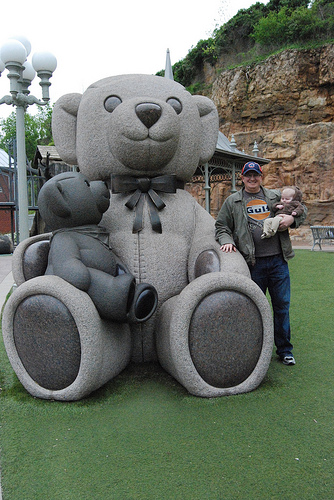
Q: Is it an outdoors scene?
A: Yes, it is outdoors.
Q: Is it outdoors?
A: Yes, it is outdoors.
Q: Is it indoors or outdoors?
A: It is outdoors.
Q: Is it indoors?
A: No, it is outdoors.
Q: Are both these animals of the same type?
A: Yes, all the animals are bears.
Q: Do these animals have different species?
A: No, all the animals are bears.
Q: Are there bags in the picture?
A: No, there are no bags.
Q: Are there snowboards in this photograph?
A: No, there are no snowboards.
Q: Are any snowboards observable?
A: No, there are no snowboards.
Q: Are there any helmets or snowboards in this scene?
A: No, there are no snowboards or helmets.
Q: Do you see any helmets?
A: No, there are no helmets.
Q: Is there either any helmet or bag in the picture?
A: No, there are no helmets or bags.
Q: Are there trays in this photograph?
A: No, there are no trays.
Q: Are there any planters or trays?
A: No, there are no trays or planters.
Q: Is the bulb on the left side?
A: Yes, the bulb is on the left of the image.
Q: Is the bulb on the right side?
A: No, the bulb is on the left of the image.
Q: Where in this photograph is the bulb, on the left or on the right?
A: The bulb is on the left of the image.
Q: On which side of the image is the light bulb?
A: The light bulb is on the left of the image.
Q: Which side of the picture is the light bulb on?
A: The light bulb is on the left of the image.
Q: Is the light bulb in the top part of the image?
A: Yes, the light bulb is in the top of the image.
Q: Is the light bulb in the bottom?
A: No, the light bulb is in the top of the image.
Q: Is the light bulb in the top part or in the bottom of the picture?
A: The light bulb is in the top of the image.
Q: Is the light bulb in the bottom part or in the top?
A: The light bulb is in the top of the image.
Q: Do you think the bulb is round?
A: Yes, the bulb is round.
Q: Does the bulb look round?
A: Yes, the bulb is round.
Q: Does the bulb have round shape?
A: Yes, the bulb is round.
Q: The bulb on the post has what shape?
A: The light bulb is round.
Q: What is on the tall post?
A: The bulb is on the post.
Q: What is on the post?
A: The bulb is on the post.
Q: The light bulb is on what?
A: The light bulb is on the post.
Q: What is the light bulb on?
A: The light bulb is on the post.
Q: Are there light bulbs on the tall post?
A: Yes, there is a light bulb on the post.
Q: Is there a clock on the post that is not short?
A: No, there is a light bulb on the post.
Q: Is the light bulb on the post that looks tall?
A: Yes, the light bulb is on the post.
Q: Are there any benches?
A: Yes, there is a bench.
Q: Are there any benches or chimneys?
A: Yes, there is a bench.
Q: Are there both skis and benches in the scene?
A: No, there is a bench but no skis.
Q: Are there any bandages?
A: No, there are no bandages.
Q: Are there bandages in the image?
A: No, there are no bandages.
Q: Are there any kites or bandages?
A: No, there are no bandages or kites.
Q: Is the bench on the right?
A: Yes, the bench is on the right of the image.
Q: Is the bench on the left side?
A: No, the bench is on the right of the image.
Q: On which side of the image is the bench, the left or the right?
A: The bench is on the right of the image.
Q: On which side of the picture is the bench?
A: The bench is on the right of the image.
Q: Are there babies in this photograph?
A: Yes, there is a baby.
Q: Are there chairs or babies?
A: Yes, there is a baby.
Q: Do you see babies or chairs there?
A: Yes, there is a baby.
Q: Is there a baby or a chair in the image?
A: Yes, there is a baby.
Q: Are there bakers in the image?
A: No, there are no bakers.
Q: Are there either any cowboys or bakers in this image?
A: No, there are no bakers or cowboys.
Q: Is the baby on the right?
A: Yes, the baby is on the right of the image.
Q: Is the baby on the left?
A: No, the baby is on the right of the image.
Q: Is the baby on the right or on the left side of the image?
A: The baby is on the right of the image.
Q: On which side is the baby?
A: The baby is on the right of the image.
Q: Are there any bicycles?
A: No, there are no bicycles.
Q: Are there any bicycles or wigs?
A: No, there are no bicycles or wigs.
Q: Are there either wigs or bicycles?
A: No, there are no bicycles or wigs.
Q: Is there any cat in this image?
A: No, there are no cats.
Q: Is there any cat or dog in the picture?
A: No, there are no cats or dogs.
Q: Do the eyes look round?
A: Yes, the eyes are round.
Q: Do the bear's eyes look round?
A: Yes, the eyes are round.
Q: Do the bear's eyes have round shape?
A: Yes, the eyes are round.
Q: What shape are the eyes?
A: The eyes are round.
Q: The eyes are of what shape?
A: The eyes are round.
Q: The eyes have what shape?
A: The eyes are round.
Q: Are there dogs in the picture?
A: No, there are no dogs.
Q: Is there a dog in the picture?
A: No, there are no dogs.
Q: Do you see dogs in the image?
A: No, there are no dogs.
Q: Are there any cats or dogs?
A: No, there are no dogs or cats.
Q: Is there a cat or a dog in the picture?
A: No, there are no dogs or cats.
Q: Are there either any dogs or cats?
A: No, there are no dogs or cats.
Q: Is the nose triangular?
A: Yes, the nose is triangular.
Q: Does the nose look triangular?
A: Yes, the nose is triangular.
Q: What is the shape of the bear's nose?
A: The nose is triangular.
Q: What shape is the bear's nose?
A: The nose is triangular.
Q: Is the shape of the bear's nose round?
A: No, the nose is triangular.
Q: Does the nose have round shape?
A: No, the nose is triangular.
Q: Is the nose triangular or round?
A: The nose is triangular.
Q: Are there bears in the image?
A: Yes, there is a bear.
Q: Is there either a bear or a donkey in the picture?
A: Yes, there is a bear.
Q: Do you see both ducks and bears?
A: No, there is a bear but no ducks.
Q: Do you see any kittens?
A: No, there are no kittens.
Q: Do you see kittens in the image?
A: No, there are no kittens.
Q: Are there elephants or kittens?
A: No, there are no kittens or elephants.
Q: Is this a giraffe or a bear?
A: This is a bear.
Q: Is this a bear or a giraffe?
A: This is a bear.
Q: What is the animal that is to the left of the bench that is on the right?
A: The animal is a bear.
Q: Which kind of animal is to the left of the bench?
A: The animal is a bear.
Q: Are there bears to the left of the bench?
A: Yes, there is a bear to the left of the bench.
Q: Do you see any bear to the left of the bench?
A: Yes, there is a bear to the left of the bench.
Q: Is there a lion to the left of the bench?
A: No, there is a bear to the left of the bench.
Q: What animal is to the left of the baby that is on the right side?
A: The animal is a bear.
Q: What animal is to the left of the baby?
A: The animal is a bear.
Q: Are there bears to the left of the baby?
A: Yes, there is a bear to the left of the baby.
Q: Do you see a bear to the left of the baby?
A: Yes, there is a bear to the left of the baby.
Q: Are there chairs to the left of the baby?
A: No, there is a bear to the left of the baby.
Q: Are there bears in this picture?
A: Yes, there is a bear.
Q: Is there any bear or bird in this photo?
A: Yes, there is a bear.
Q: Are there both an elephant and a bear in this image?
A: No, there is a bear but no elephants.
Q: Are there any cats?
A: No, there are no cats.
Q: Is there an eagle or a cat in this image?
A: No, there are no cats or eagles.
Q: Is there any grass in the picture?
A: Yes, there is grass.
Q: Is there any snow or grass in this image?
A: Yes, there is grass.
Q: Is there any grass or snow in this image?
A: Yes, there is grass.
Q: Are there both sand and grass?
A: No, there is grass but no sand.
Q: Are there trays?
A: No, there are no trays.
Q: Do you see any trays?
A: No, there are no trays.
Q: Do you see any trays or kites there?
A: No, there are no trays or kites.